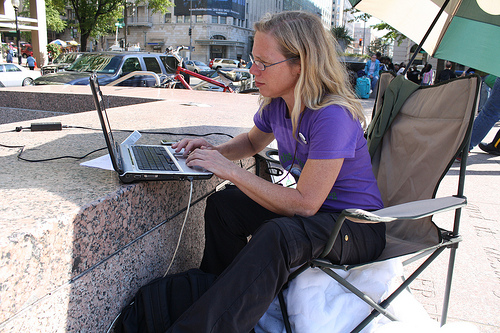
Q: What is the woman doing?
A: Typing on her laptop.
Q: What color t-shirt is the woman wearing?
A: A purple t-shirt.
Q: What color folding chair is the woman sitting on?
A: A brown folding chair.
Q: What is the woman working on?
A: The woman is working on a laptop.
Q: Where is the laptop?
A: The laptop computer is on a stone wall.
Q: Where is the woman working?
A: The woman is working outdoors.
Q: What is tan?
A: The folding chair.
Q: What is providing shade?
A: Umbrella.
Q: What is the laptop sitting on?
A: Stone wall.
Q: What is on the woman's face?
A: Eyeglasses.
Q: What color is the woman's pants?
A: Black.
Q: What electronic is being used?
A: Laptop.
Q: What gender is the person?
A: Female.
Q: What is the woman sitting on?
A: Foldable chair.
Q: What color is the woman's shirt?
A: Purple.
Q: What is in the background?
A: Cars and buildings.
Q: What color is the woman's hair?
A: Blonde.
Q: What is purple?
A: Woman's shirt.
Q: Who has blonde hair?
A: The woman.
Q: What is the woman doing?
A: Looking at laptop.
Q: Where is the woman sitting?
A: On a chair.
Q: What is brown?
A: The chair.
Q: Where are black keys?
A: On a laptop.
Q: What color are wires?
A: Black.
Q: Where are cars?
A: On the road.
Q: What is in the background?
A: Buildings.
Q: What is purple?
A: Woman's shirt.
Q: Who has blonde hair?
A: The woman.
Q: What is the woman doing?
A: Typing on laptop.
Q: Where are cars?
A: On the road.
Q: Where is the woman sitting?
A: On a chair.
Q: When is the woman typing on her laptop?
A: Now.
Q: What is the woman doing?
A: Typing.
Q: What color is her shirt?
A: Blue.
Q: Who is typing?
A: A woman.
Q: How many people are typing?
A: One.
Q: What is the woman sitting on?
A: A lawn chair.